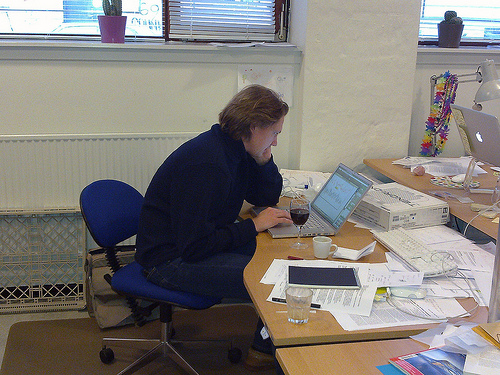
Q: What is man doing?
A: Working on laptop.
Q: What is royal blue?
A: Desk chair.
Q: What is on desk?
A: White papers.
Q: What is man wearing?
A: Blue pullover.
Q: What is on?
A: Laptop.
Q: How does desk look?
A: Scattered with papers.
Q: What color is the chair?
A: Blue.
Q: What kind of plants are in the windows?
A: Cacti.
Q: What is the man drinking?
A: Wine.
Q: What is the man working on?
A: A laptop.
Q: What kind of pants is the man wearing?
A: Jeans.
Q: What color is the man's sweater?
A: Blue.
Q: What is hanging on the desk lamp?
A: Leis.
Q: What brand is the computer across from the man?
A: Apple.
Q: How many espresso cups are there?
A: 1.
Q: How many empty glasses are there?
A: 1.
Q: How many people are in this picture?
A: One.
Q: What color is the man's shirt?
A: Blue.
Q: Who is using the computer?
A: The person in black.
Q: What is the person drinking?
A: Wine.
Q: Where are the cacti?
A: On the windowsills.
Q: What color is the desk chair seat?
A: Blue.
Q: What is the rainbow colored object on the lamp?
A: A lei.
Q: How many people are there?
A: 1.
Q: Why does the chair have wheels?
A: To move around the office.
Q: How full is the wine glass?
A: About half full.